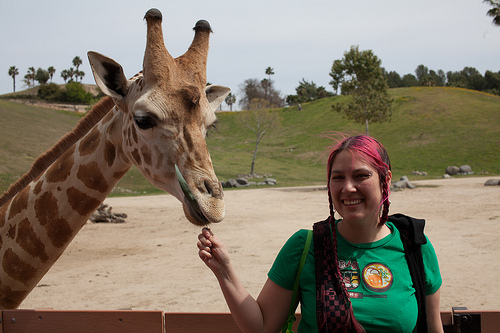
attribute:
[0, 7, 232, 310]
giraffe — left side, here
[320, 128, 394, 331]
hair — pink, brown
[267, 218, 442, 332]
shirt — green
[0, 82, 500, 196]
hill — grassy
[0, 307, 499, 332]
fence — wooden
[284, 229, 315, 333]
strap — green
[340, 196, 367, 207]
smile — wide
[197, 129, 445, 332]
woman — smiling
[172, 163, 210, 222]
leaf — green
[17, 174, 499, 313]
area — dirt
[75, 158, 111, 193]
spot — brown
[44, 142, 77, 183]
spot — brown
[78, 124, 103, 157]
spot — brown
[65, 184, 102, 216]
spot — brown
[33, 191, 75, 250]
spot — brown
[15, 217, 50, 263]
spot — brown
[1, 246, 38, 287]
spot — brown